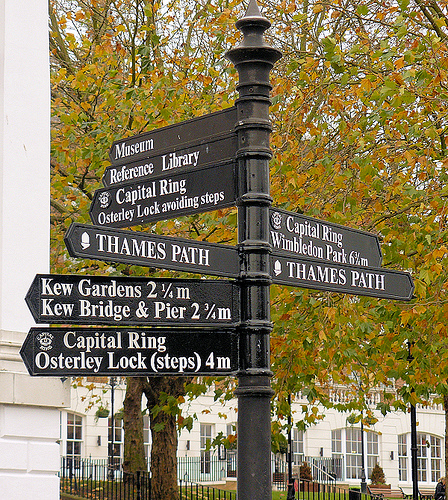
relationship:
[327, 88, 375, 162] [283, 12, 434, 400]
leaves on tree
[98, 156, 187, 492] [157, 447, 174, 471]
tree has bark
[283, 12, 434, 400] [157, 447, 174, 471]
tree has bark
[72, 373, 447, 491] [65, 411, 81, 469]
building has window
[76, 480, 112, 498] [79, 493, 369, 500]
leaves on ground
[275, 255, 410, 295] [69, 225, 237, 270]
thames path direction sign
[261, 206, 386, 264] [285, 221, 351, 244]
sign for capitol ring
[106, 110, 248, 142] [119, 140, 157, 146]
sign for museum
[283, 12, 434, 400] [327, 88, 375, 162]
tree has leaves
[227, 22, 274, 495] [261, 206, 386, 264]
pole has sign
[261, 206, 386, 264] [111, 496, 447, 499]
sign for street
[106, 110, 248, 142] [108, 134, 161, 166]
sign on arrow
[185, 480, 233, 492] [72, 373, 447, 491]
grass in front of building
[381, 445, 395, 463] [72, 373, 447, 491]
light on building